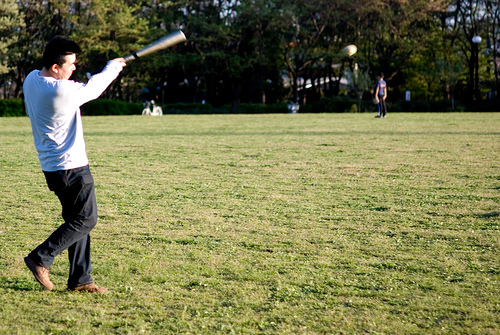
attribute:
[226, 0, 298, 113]
tree — green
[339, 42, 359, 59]
baseball — white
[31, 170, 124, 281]
pants — black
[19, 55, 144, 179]
shirt — gray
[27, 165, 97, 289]
pants — black, baggy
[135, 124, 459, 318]
grass — Short, Freshly Mowed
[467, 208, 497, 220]
shadow — small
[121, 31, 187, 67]
baseball bat — gray, black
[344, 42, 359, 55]
baseball — small, white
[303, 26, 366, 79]
baseball — Regulation, White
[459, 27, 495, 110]
lamp pole — tall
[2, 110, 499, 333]
field — green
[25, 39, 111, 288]
man shoe — brown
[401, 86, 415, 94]
sign — blue, white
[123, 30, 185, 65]
silver bat — lifted up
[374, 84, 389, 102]
arms — down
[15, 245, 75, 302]
shoe — Brown, Slanted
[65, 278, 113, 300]
shoe — brown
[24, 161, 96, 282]
pants — black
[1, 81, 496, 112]
bushes — squared off